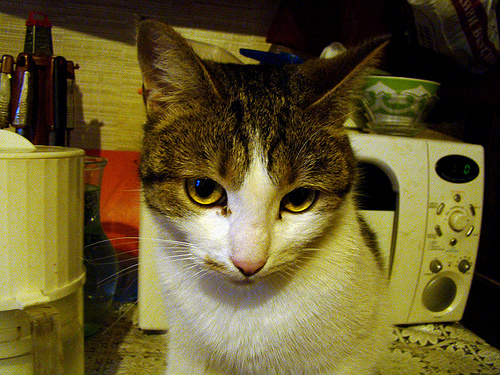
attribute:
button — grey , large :
[411, 244, 496, 306]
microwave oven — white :
[353, 116, 490, 334]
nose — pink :
[231, 249, 271, 278]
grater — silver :
[14, 21, 84, 88]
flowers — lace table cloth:
[382, 319, 460, 372]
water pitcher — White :
[0, 124, 92, 374]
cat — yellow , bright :
[116, 32, 446, 329]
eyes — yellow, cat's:
[177, 172, 327, 221]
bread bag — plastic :
[423, 2, 468, 74]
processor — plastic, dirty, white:
[0, 132, 89, 373]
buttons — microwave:
[426, 195, 473, 281]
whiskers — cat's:
[76, 214, 353, 318]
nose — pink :
[228, 250, 267, 281]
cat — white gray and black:
[123, 30, 434, 372]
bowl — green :
[353, 75, 440, 132]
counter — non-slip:
[382, 327, 495, 373]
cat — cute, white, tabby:
[134, 18, 393, 373]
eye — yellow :
[280, 184, 319, 213]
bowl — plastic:
[358, 93, 434, 138]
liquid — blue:
[80, 182, 119, 337]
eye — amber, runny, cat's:
[281, 183, 320, 214]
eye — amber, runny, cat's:
[181, 177, 226, 210]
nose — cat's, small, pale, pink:
[230, 252, 267, 279]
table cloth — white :
[416, 310, 444, 351]